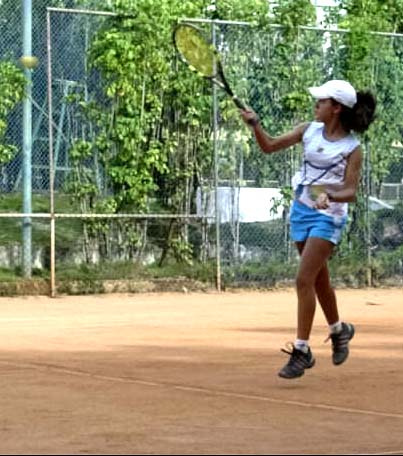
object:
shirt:
[294, 120, 360, 220]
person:
[240, 79, 376, 379]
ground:
[11, 353, 402, 455]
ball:
[20, 53, 37, 69]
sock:
[294, 339, 310, 355]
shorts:
[288, 197, 345, 245]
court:
[0, 290, 402, 455]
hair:
[346, 90, 379, 135]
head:
[314, 79, 356, 126]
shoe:
[327, 320, 354, 364]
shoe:
[278, 346, 317, 379]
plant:
[68, 2, 209, 259]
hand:
[240, 109, 258, 129]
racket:
[171, 22, 250, 113]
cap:
[305, 78, 355, 108]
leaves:
[112, 34, 144, 97]